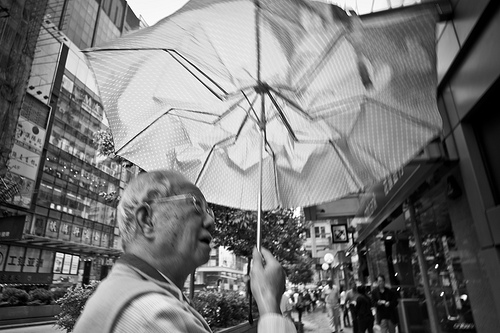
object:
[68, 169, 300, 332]
man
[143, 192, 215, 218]
eyeglasses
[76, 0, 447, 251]
umbrella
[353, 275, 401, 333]
people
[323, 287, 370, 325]
corner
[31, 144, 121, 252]
windows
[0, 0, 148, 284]
building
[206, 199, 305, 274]
tree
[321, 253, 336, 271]
lights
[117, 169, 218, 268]
head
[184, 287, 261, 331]
bushes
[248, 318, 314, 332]
street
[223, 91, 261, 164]
wire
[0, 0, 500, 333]
photo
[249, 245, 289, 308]
hand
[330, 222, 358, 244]
signs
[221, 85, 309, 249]
support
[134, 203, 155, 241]
ear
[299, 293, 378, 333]
sidewalk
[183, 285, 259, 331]
shrubs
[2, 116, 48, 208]
banner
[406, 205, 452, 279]
window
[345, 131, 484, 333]
store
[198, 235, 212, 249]
mouth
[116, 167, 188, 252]
hair